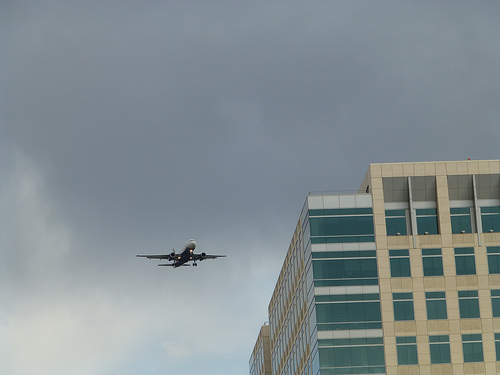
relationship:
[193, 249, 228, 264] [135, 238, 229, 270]
wing of airplane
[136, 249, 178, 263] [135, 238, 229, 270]
wing of airplane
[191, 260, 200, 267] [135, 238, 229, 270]
wheels of airplane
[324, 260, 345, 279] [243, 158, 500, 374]
window of building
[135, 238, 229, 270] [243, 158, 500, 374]
airplane near building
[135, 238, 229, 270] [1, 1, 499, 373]
airplane flying across sky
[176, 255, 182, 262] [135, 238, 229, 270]
light of airplane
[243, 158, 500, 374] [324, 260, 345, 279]
building with window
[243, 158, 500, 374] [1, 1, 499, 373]
building below sky